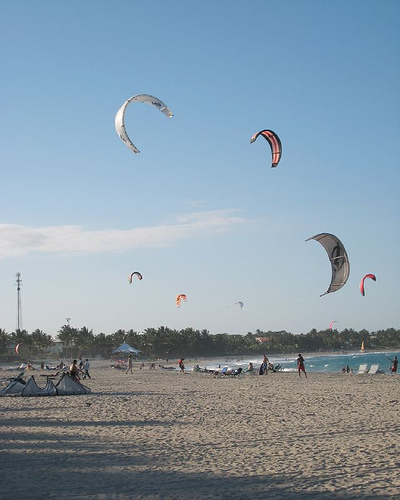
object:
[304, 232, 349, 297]
kite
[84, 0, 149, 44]
sky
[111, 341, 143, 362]
tent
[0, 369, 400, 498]
beach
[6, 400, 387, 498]
sand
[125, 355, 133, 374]
person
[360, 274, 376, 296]
kite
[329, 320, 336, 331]
kite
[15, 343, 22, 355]
kite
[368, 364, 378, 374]
chairs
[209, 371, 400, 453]
sand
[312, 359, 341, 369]
water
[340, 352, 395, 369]
water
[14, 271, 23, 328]
tower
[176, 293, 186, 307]
kite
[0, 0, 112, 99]
sky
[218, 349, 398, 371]
water